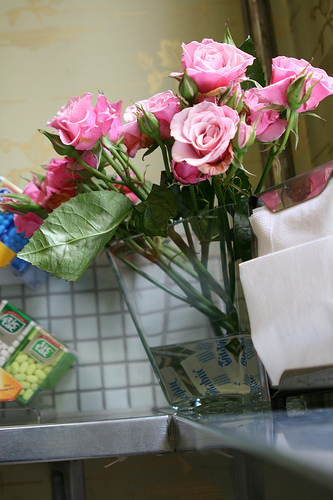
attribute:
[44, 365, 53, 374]
tic tac — white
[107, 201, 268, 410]
glass vase — clear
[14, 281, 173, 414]
ceramic tile — white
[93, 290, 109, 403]
grout — gray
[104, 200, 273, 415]
vase — clear, glass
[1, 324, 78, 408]
tic tacs — yellow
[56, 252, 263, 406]
countertop — silver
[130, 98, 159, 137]
rose bud — unopened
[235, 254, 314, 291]
paper — curled, white, sheet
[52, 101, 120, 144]
flower — pink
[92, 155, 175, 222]
stem — green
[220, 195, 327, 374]
towels — white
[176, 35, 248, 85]
flower — pink 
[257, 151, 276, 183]
stem — green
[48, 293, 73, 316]
tile — white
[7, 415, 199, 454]
table — stainless steel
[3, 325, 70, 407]
container — plastic 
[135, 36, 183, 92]
gold accents — gold 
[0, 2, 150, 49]
gold accents — gold 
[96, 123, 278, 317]
stem — green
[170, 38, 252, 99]
rose — light, pink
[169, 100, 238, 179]
rose — pink, light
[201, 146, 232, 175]
petal — brown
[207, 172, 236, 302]
stem — green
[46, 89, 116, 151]
flower — pink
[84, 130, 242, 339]
stem — green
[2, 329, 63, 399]
tacs — yellow tic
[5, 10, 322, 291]
flown — pink 